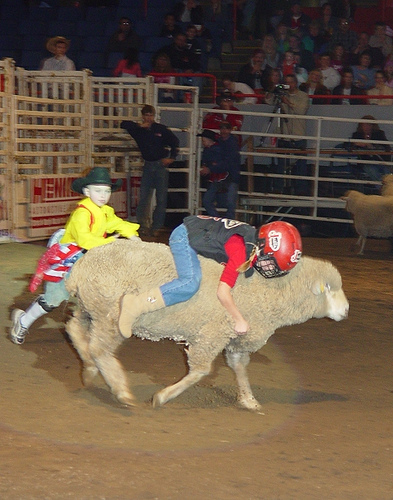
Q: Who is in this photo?
A: Two little boys.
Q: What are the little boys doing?
A: Riding animals.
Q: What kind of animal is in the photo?
A: Sheep.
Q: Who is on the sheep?
A: A boy.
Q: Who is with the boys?
A: A man standing.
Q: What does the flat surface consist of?
A: The ground is made of dirt.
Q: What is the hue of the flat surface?
A: The ground is brown.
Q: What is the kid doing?
A: Riding a sheep.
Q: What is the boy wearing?
A: A cowboy hat.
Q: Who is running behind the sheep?
A: A little boy.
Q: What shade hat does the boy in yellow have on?
A: Black.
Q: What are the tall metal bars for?
A: To retain the animals.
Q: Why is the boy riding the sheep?
A: It's a competition.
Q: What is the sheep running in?
A: Dirt on the ground.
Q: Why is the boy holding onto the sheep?
A: So he doesn't fall.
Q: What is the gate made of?
A: Metal.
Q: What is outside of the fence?
A: Stands.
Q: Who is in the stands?
A: An audience.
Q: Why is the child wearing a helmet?
A: For protection.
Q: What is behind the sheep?
A: A child.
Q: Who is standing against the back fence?
A: A man.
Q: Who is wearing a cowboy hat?
A: The child on the left.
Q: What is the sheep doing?
A: Running.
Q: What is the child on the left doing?
A: Chasing the sheep.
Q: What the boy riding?
A: The lamb.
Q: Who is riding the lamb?
A: The little boy.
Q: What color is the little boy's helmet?
A: Red.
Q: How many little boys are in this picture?
A: Two.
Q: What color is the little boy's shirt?
A: Red and blue.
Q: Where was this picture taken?
A: A rodeo.